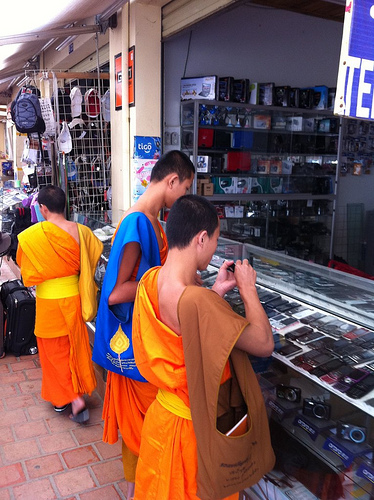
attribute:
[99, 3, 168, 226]
wall — coatings , color , cream 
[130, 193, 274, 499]
man — young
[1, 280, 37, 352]
suitcase — black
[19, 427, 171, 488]
floor — brown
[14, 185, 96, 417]
person — shoulder, color 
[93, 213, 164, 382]
bag — blue 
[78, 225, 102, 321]
bag — YELLOW 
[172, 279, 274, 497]
bag — brown, shoulder 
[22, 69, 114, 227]
mesh — wire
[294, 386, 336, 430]
cameras — displayed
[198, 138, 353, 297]
case — GLASS, LONG 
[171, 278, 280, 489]
bag — yellow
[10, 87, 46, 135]
backpack — GREY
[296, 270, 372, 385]
mobile phones — displayed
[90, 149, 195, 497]
man — young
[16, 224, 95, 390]
sari — orange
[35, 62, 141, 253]
rack — metal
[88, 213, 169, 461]
robe — orange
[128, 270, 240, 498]
robe — orange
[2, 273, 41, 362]
suitcase — black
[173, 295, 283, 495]
bag — brown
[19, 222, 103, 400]
clothes — yellow, orange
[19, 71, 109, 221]
rack — white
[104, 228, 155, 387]
bag — BLUE  